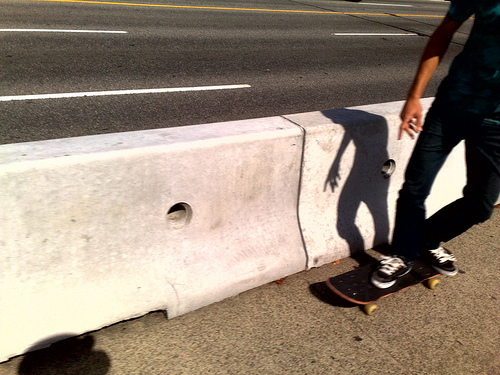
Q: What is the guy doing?
A: Skating.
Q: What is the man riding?
A: A skateboard.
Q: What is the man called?
A: A skateboarder.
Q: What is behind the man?
A: Concrete median.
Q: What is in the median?
A: Holes.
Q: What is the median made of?
A: Concrete.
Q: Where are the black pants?
A: On the skateboarder.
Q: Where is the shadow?
A: On the median.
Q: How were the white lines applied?
A: Paint.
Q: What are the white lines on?
A: The highway.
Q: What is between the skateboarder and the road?
A: Road barriers.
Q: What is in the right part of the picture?
A: A person on a skateboard.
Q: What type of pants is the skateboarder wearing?
A: Tight black jeans.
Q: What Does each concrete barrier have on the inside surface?
A: A hole.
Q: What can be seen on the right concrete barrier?
A: The skateboarder's shadow.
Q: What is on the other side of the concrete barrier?
A: The road.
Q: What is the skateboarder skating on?
A: The sidewalk.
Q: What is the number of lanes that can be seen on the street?
A: Three lanes.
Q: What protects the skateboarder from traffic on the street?
A: The concrete barriers.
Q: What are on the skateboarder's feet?
A: Black shoes with white shoelaces.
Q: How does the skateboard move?
A: Using four wheels.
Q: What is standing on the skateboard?
A: Aside from not being able to see the head, it is a human.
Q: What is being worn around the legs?
A: Black pants.